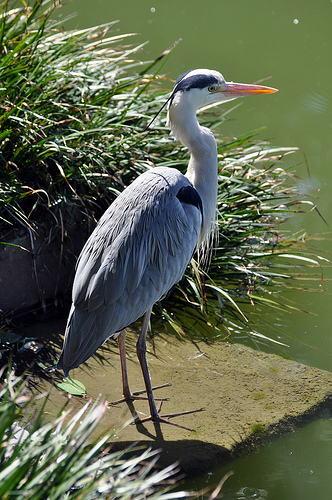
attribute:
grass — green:
[216, 139, 303, 347]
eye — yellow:
[206, 81, 219, 94]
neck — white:
[159, 115, 255, 208]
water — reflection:
[237, 13, 306, 66]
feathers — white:
[69, 167, 192, 311]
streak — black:
[176, 184, 203, 228]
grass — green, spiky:
[0, 1, 331, 395]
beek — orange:
[203, 71, 258, 121]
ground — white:
[308, 87, 318, 97]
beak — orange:
[223, 80, 278, 100]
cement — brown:
[34, 316, 331, 475]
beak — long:
[218, 43, 303, 122]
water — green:
[259, 13, 305, 72]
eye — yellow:
[207, 83, 217, 92]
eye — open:
[204, 83, 222, 94]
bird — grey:
[55, 66, 278, 431]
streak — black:
[169, 74, 215, 109]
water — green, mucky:
[141, 403, 319, 497]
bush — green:
[5, 10, 132, 182]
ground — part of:
[235, 372, 269, 399]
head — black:
[170, 55, 250, 137]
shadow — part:
[120, 436, 240, 472]